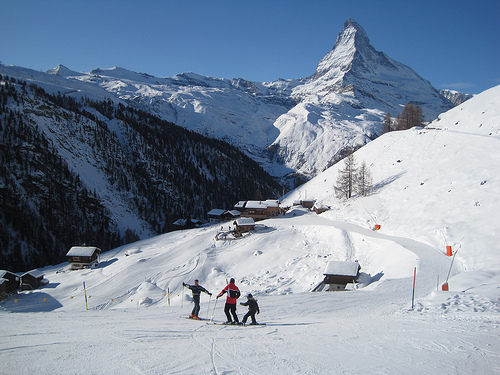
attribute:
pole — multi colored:
[405, 259, 421, 314]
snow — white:
[269, 199, 499, 341]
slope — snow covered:
[265, 130, 499, 367]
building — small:
[56, 237, 108, 274]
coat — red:
[211, 280, 243, 304]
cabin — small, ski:
[322, 258, 361, 283]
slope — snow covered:
[176, 273, 268, 330]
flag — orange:
[440, 240, 460, 258]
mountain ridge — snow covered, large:
[137, 64, 187, 91]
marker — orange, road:
[441, 243, 455, 259]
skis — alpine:
[224, 322, 251, 330]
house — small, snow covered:
[320, 255, 362, 286]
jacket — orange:
[213, 284, 248, 303]